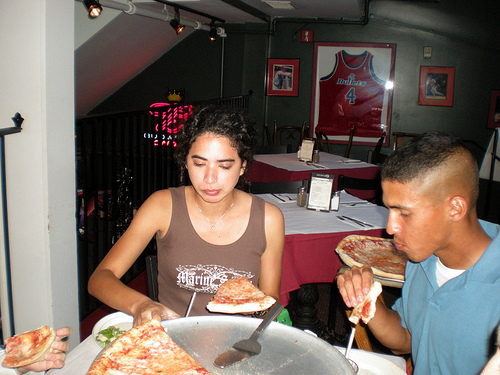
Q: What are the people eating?
A: Pizza.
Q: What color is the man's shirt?
A: Blue.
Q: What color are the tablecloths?
A: Red.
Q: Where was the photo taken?
A: Baltimore.